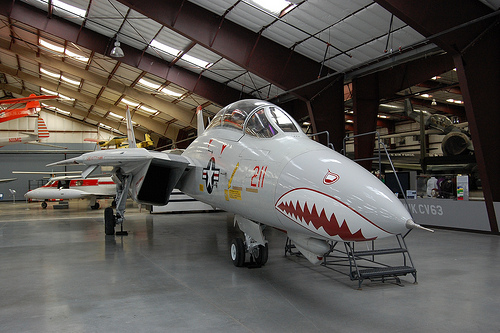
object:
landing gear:
[227, 215, 274, 272]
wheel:
[104, 206, 116, 235]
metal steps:
[349, 263, 417, 280]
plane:
[41, 102, 70, 115]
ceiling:
[0, 1, 490, 149]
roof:
[0, 0, 500, 148]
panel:
[247, 0, 296, 17]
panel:
[148, 39, 213, 70]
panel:
[133, 77, 175, 101]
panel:
[120, 98, 157, 120]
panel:
[39, 61, 82, 90]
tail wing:
[26, 92, 41, 110]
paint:
[273, 187, 394, 242]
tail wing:
[35, 116, 50, 136]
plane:
[0, 118, 50, 148]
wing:
[46, 146, 195, 207]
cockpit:
[201, 98, 303, 138]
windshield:
[246, 109, 278, 138]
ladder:
[343, 238, 419, 290]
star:
[205, 161, 217, 189]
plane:
[23, 168, 119, 210]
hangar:
[0, 0, 496, 333]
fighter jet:
[43, 99, 435, 266]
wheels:
[229, 237, 246, 268]